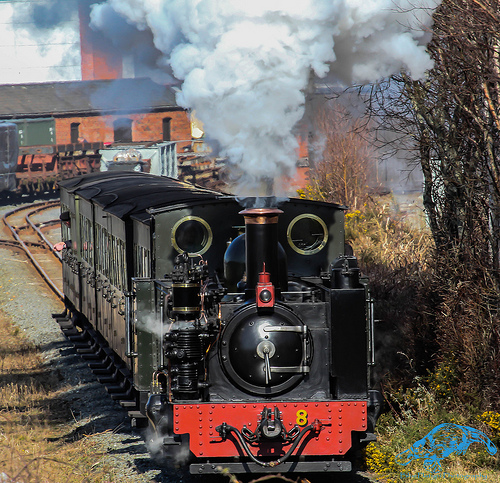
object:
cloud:
[0, 0, 500, 210]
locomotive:
[52, 170, 381, 475]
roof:
[0, 77, 178, 118]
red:
[173, 401, 368, 458]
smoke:
[0, 0, 500, 209]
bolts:
[175, 406, 179, 410]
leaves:
[365, 442, 392, 467]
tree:
[324, 0, 500, 351]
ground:
[24, 308, 47, 332]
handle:
[124, 291, 138, 358]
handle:
[366, 298, 382, 366]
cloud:
[0, 0, 335, 169]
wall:
[139, 116, 158, 135]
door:
[113, 118, 133, 142]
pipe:
[238, 207, 284, 302]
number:
[296, 409, 308, 426]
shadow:
[0, 340, 161, 474]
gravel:
[37, 325, 53, 343]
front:
[146, 269, 377, 470]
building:
[0, 76, 312, 194]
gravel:
[9, 288, 47, 315]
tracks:
[2, 200, 64, 300]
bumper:
[173, 402, 367, 458]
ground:
[0, 252, 16, 266]